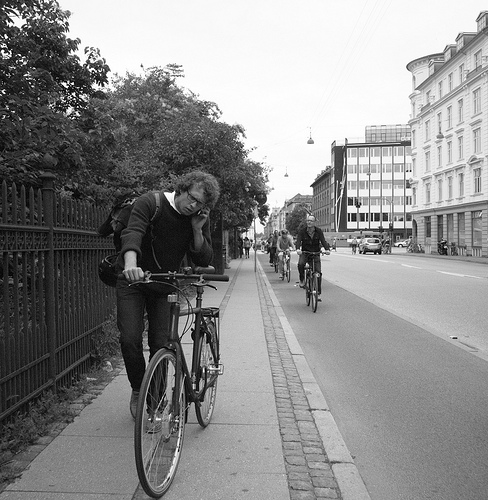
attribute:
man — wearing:
[108, 166, 221, 439]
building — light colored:
[385, 31, 473, 253]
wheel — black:
[132, 343, 187, 498]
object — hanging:
[302, 137, 318, 149]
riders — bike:
[260, 215, 332, 300]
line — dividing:
[376, 241, 462, 296]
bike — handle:
[114, 248, 268, 471]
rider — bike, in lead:
[288, 211, 324, 300]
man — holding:
[139, 159, 237, 377]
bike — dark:
[131, 265, 228, 498]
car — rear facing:
[359, 236, 384, 258]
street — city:
[256, 248, 486, 498]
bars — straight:
[142, 270, 234, 288]